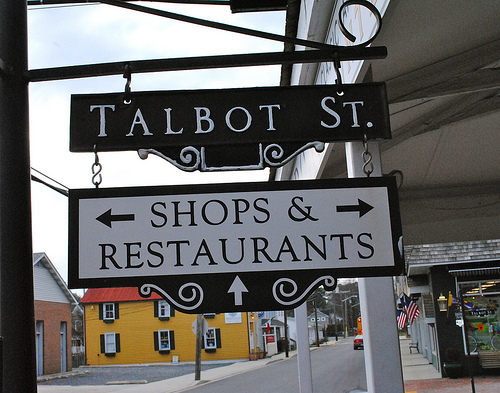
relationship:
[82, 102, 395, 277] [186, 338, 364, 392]
signs on road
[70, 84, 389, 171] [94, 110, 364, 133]
signage has writing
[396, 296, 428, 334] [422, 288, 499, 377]
flags front of shops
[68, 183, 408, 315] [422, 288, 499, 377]
signs showind shops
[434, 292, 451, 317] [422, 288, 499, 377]
lantern by shops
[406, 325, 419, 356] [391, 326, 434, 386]
bench on sidewalk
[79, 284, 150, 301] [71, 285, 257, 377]
roof on building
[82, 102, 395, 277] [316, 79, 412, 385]
signs on pole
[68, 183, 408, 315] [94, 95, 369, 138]
signs says talbot st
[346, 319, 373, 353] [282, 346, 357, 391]
car on road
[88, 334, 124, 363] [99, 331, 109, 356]
window has shutters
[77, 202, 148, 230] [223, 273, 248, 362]
arrow pointing up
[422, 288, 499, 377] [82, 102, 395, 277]
shops has signs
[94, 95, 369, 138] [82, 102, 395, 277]
talbot st on signs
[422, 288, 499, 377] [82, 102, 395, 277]
shops on signs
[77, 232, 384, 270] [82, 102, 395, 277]
restaurants on signs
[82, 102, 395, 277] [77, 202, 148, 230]
signs has arrow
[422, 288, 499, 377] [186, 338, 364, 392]
stores on road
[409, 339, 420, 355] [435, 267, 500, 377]
bench by shops